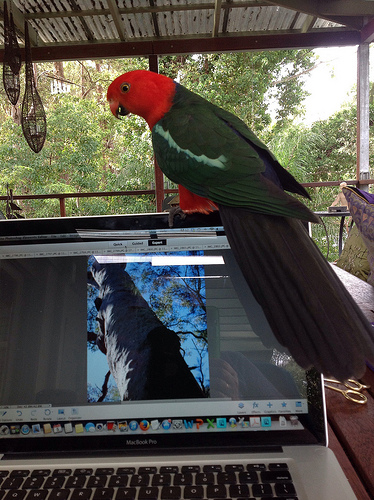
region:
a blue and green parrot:
[106, 69, 372, 389]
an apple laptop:
[0, 210, 358, 497]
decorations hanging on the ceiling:
[0, 0, 43, 152]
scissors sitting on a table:
[324, 379, 368, 404]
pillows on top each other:
[336, 183, 373, 281]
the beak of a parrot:
[110, 96, 130, 118]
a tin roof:
[0, 0, 370, 43]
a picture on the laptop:
[88, 255, 209, 396]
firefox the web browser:
[138, 420, 149, 430]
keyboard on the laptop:
[3, 468, 296, 497]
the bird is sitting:
[72, 64, 303, 217]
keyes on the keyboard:
[2, 462, 285, 491]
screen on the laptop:
[4, 245, 285, 393]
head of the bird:
[110, 71, 176, 122]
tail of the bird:
[244, 190, 358, 346]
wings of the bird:
[196, 141, 282, 185]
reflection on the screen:
[88, 237, 218, 279]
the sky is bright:
[311, 77, 346, 106]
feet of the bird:
[162, 202, 193, 224]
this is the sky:
[319, 77, 332, 91]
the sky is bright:
[314, 90, 325, 109]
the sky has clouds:
[310, 85, 325, 110]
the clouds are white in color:
[307, 99, 321, 116]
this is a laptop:
[10, 221, 351, 498]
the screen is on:
[77, 246, 219, 403]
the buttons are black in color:
[121, 470, 265, 496]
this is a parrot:
[107, 69, 299, 236]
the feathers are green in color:
[181, 127, 220, 163]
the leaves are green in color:
[65, 124, 85, 150]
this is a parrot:
[94, 59, 275, 231]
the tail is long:
[239, 236, 338, 326]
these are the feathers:
[163, 109, 242, 176]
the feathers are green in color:
[171, 112, 245, 167]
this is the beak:
[107, 103, 133, 122]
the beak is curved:
[105, 102, 132, 120]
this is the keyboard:
[173, 460, 262, 498]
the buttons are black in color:
[186, 464, 242, 498]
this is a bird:
[102, 73, 314, 271]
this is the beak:
[108, 95, 121, 120]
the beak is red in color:
[107, 102, 119, 113]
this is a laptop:
[51, 269, 221, 462]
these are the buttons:
[149, 474, 292, 497]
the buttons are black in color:
[195, 461, 248, 498]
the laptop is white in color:
[291, 453, 319, 475]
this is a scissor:
[337, 373, 370, 409]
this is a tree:
[241, 63, 328, 121]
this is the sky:
[313, 78, 339, 103]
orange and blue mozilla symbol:
[139, 417, 149, 432]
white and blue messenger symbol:
[83, 419, 95, 434]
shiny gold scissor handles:
[321, 375, 370, 405]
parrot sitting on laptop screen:
[105, 67, 373, 382]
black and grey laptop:
[1, 209, 359, 499]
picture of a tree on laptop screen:
[84, 251, 212, 400]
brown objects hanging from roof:
[1, 1, 46, 154]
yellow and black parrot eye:
[118, 80, 129, 92]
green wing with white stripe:
[149, 111, 264, 187]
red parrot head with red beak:
[105, 69, 171, 121]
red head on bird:
[101, 65, 181, 132]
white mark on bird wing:
[152, 120, 232, 172]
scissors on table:
[318, 371, 371, 406]